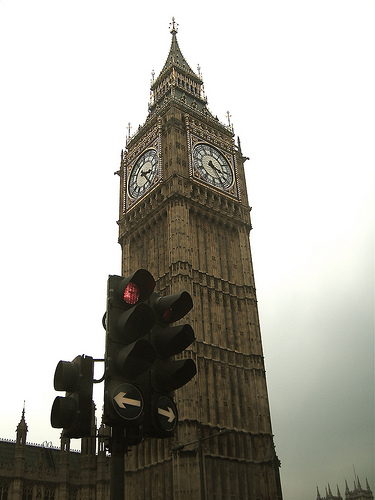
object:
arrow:
[111, 388, 143, 411]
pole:
[108, 432, 128, 498]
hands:
[208, 161, 220, 173]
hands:
[208, 157, 225, 189]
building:
[0, 14, 281, 499]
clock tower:
[107, 13, 282, 498]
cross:
[118, 118, 138, 137]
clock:
[191, 141, 235, 190]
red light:
[117, 277, 143, 305]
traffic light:
[114, 265, 157, 425]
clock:
[125, 147, 160, 194]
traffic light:
[48, 350, 98, 444]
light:
[104, 274, 200, 399]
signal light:
[119, 268, 199, 394]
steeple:
[146, 18, 205, 108]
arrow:
[158, 405, 176, 423]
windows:
[22, 480, 62, 499]